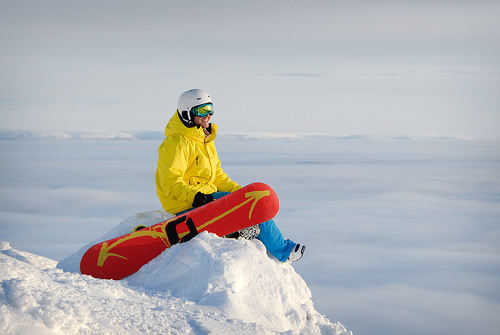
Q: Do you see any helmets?
A: Yes, there is a helmet.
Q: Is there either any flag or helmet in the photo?
A: Yes, there is a helmet.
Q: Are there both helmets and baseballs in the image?
A: No, there is a helmet but no baseballs.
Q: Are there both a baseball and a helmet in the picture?
A: No, there is a helmet but no baseballs.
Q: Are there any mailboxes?
A: No, there are no mailboxes.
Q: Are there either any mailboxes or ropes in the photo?
A: No, there are no mailboxes or ropes.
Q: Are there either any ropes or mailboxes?
A: No, there are no mailboxes or ropes.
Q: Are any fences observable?
A: No, there are no fences.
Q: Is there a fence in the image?
A: No, there are no fences.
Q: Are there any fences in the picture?
A: No, there are no fences.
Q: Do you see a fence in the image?
A: No, there are no fences.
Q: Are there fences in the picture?
A: No, there are no fences.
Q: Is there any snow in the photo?
A: Yes, there is snow.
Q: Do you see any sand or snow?
A: Yes, there is snow.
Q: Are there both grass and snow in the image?
A: No, there is snow but no grass.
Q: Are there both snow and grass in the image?
A: No, there is snow but no grass.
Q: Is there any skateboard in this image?
A: No, there are no skateboards.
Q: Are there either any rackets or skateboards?
A: No, there are no skateboards or rackets.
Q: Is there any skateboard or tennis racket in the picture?
A: No, there are no skateboards or rackets.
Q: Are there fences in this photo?
A: No, there are no fences.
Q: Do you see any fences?
A: No, there are no fences.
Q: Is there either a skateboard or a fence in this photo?
A: No, there are no fences or skateboards.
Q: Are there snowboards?
A: Yes, there is a snowboard.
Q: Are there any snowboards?
A: Yes, there is a snowboard.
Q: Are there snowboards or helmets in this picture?
A: Yes, there is a snowboard.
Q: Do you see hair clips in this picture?
A: No, there are no hair clips.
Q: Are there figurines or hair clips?
A: No, there are no hair clips or figurines.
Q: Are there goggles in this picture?
A: Yes, there are goggles.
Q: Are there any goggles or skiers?
A: Yes, there are goggles.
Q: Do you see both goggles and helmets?
A: Yes, there are both goggles and a helmet.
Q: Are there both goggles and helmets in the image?
A: Yes, there are both goggles and a helmet.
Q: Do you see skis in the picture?
A: No, there are no skis.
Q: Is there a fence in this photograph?
A: No, there are no fences.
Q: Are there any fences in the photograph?
A: No, there are no fences.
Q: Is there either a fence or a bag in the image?
A: No, there are no fences or bags.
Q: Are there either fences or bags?
A: No, there are no fences or bags.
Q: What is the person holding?
A: The person is holding the snowboard.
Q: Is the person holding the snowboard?
A: Yes, the person is holding the snowboard.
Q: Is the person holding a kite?
A: No, the person is holding the snowboard.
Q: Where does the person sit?
A: The person sits in the snow.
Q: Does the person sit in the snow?
A: Yes, the person sits in the snow.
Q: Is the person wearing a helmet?
A: Yes, the person is wearing a helmet.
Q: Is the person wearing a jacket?
A: Yes, the person is wearing a jacket.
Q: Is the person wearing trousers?
A: Yes, the person is wearing trousers.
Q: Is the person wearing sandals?
A: No, the person is wearing trousers.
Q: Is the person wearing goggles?
A: Yes, the person is wearing goggles.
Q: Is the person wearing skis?
A: No, the person is wearing goggles.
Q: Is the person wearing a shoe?
A: Yes, the person is wearing a shoe.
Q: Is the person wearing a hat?
A: No, the person is wearing a shoe.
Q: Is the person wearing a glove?
A: Yes, the person is wearing a glove.